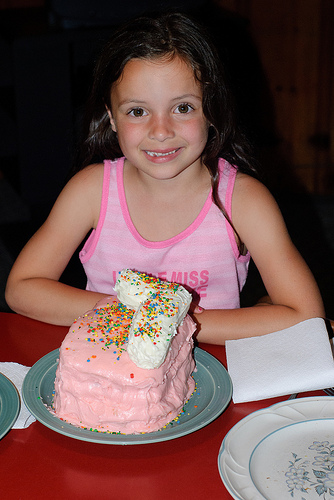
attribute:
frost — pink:
[51, 270, 195, 432]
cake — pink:
[50, 269, 203, 433]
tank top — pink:
[73, 154, 255, 313]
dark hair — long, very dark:
[76, 11, 267, 259]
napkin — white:
[221, 309, 332, 397]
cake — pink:
[17, 269, 229, 441]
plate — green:
[21, 313, 251, 455]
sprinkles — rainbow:
[92, 304, 128, 349]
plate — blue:
[199, 398, 224, 409]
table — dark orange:
[7, 306, 330, 467]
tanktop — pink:
[88, 151, 250, 311]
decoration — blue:
[284, 433, 330, 498]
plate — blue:
[21, 347, 233, 443]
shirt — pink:
[68, 153, 253, 322]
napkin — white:
[223, 316, 333, 409]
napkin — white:
[225, 317, 332, 401]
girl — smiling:
[101, 33, 223, 210]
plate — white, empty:
[211, 395, 333, 499]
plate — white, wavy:
[218, 397, 330, 498]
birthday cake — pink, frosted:
[51, 265, 198, 435]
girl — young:
[21, 21, 292, 431]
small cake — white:
[114, 262, 197, 353]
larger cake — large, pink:
[34, 290, 221, 440]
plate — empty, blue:
[1, 370, 21, 440]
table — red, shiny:
[0, 313, 333, 498]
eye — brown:
[123, 104, 152, 117]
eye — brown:
[173, 101, 196, 115]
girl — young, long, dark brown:
[0, 15, 327, 342]